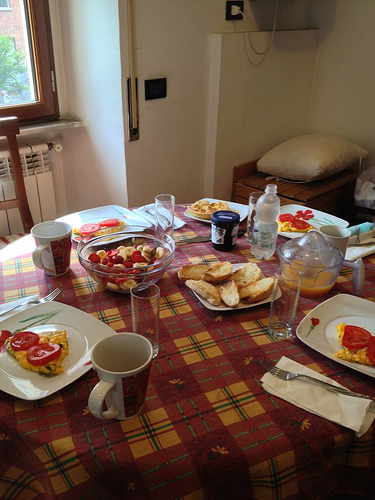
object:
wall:
[172, 38, 253, 150]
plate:
[0, 300, 118, 402]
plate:
[193, 260, 282, 311]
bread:
[220, 278, 241, 308]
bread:
[239, 276, 273, 303]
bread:
[227, 263, 262, 288]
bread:
[201, 260, 232, 283]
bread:
[184, 278, 221, 307]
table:
[0, 202, 375, 477]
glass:
[130, 281, 161, 360]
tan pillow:
[256, 135, 369, 182]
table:
[230, 156, 363, 209]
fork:
[261, 358, 375, 408]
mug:
[88, 330, 152, 421]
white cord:
[230, 3, 278, 56]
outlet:
[226, 0, 244, 21]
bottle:
[251, 183, 281, 260]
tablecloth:
[175, 322, 235, 391]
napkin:
[260, 355, 374, 439]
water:
[250, 183, 281, 259]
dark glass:
[211, 210, 240, 251]